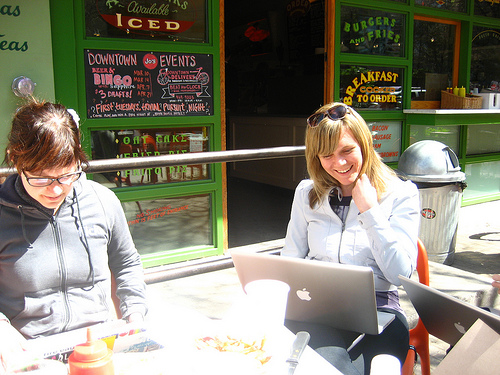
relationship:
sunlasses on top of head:
[304, 104, 359, 124] [304, 103, 387, 200]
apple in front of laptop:
[293, 284, 315, 307] [235, 239, 387, 335]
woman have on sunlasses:
[277, 105, 415, 368] [304, 104, 359, 124]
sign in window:
[335, 6, 415, 58] [319, 2, 500, 61]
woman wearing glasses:
[4, 115, 151, 345] [15, 167, 91, 190]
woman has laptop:
[277, 105, 415, 368] [235, 239, 387, 335]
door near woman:
[220, 4, 328, 221] [277, 105, 415, 368]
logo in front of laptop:
[291, 284, 321, 313] [235, 239, 387, 335]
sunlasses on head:
[304, 104, 359, 124] [304, 103, 387, 200]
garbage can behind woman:
[390, 137, 477, 272] [277, 105, 415, 368]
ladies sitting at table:
[7, 104, 418, 289] [66, 315, 314, 374]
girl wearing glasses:
[4, 115, 151, 345] [15, 167, 91, 190]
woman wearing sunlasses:
[277, 105, 415, 368] [304, 104, 359, 124]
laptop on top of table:
[235, 239, 387, 335] [66, 315, 314, 374]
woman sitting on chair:
[277, 105, 415, 368] [407, 245, 449, 374]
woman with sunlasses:
[277, 105, 415, 368] [304, 104, 359, 124]